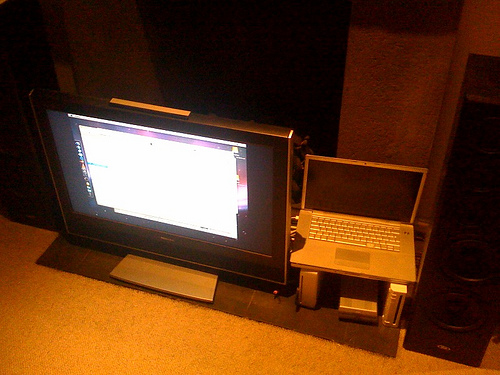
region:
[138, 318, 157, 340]
part of a floor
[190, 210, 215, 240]
part of a screen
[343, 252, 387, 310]
part of a board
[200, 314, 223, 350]
part of a floor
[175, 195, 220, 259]
part of a screen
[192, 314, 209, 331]
part of a floor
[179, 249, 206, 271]
part of a creen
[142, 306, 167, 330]
part of a floor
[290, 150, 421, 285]
a grey laptop computer stacked on hard drives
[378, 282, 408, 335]
a white hard drive on the floor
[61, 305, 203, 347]
white carpet floor of the room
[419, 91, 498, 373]
a tall black speaker on the floor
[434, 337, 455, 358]
grey logo on the black speaker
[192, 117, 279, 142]
grey metal trim of the television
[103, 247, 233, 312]
grey plastic base of the television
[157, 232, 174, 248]
grey logo on the black front of the television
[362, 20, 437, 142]
grey surface of the wall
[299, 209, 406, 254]
grey keys of the laptop computer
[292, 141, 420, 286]
the white laptop computer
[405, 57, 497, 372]
the black speaker on the carpet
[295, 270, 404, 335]
the white base under the laptop computer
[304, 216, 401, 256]
the keys on the laptop computer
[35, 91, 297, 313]
the flatscreen tv on the ground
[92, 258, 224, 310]
the silver base of the tv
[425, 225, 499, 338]
the round speakers on the black tower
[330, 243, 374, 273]
the mmouse pad on the laptop computer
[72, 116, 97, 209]
the tv with the computer toolbar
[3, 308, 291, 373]
the carpet in front of the tv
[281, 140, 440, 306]
the laptop is silver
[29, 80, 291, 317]
the monitor is on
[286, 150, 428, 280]
laptop on a mount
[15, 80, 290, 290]
a large monitor display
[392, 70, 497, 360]
speaker on the floor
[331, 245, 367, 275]
track pad of a laptop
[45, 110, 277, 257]
display of a lcd monitor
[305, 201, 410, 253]
keyboard of a laptop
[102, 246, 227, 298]
bezel of a monitor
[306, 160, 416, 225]
screen of a laptop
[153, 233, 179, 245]
logo on the lcd monitor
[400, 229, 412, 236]
power button of laptop